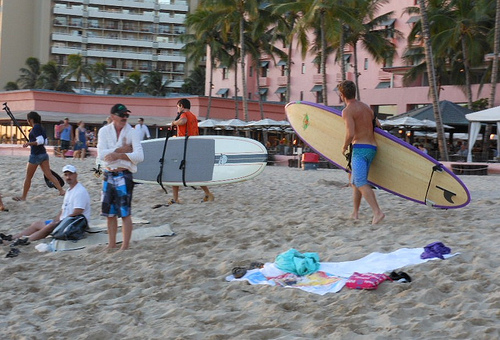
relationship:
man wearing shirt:
[164, 97, 220, 206] [175, 112, 200, 137]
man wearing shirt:
[54, 116, 76, 161] [59, 122, 72, 142]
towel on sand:
[225, 245, 457, 294] [1, 157, 499, 340]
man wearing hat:
[2, 164, 94, 245] [62, 164, 78, 175]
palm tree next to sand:
[405, 3, 489, 112] [1, 157, 499, 340]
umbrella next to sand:
[382, 111, 422, 128] [1, 157, 499, 340]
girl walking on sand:
[12, 111, 67, 202] [1, 157, 499, 340]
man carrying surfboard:
[336, 80, 386, 227] [283, 101, 471, 212]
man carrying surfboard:
[164, 97, 220, 206] [133, 136, 268, 185]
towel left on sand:
[225, 245, 457, 294] [1, 157, 499, 340]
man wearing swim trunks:
[336, 80, 386, 227] [349, 143, 377, 187]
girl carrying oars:
[12, 111, 67, 202] [3, 102, 65, 188]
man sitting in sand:
[2, 164, 94, 245] [1, 157, 499, 340]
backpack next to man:
[51, 215, 92, 244] [2, 164, 94, 245]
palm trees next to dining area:
[186, 1, 498, 107] [196, 99, 497, 161]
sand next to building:
[1, 157, 499, 340] [203, 3, 499, 151]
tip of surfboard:
[282, 99, 299, 123] [283, 101, 471, 212]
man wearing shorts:
[96, 103, 146, 251] [98, 170, 136, 220]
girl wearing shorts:
[12, 111, 67, 202] [29, 149, 51, 166]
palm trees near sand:
[186, 1, 498, 107] [1, 157, 499, 340]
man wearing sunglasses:
[96, 103, 146, 251] [114, 111, 130, 119]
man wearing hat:
[96, 103, 146, 251] [107, 102, 131, 116]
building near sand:
[203, 3, 499, 151] [1, 157, 499, 340]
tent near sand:
[465, 104, 500, 160] [1, 157, 499, 340]